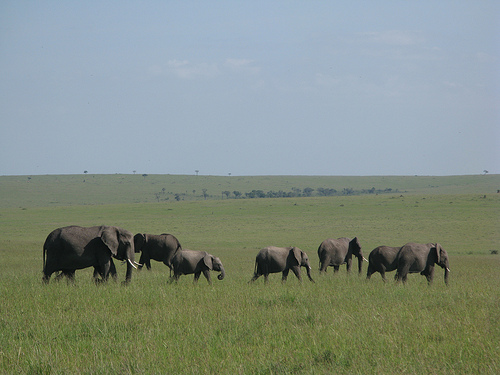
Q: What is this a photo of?
A: Elephants.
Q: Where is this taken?
A: In a field.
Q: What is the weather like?
A: Clear.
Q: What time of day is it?
A: Daytime.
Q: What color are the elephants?
A: Gray.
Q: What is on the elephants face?
A: Tusk.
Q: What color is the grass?
A: Green.